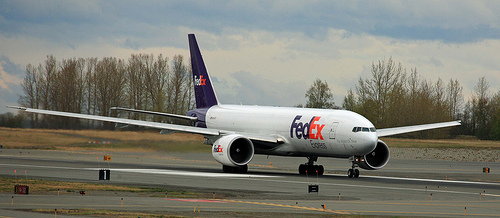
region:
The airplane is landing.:
[34, 42, 466, 189]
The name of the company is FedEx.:
[282, 114, 328, 142]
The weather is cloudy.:
[35, 6, 392, 83]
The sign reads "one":
[95, 167, 113, 184]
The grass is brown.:
[10, 130, 55, 147]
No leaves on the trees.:
[36, 60, 183, 118]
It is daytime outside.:
[38, 4, 478, 204]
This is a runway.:
[23, 135, 485, 213]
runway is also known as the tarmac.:
[76, 152, 441, 204]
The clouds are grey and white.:
[235, 15, 443, 88]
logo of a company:
[285, 111, 328, 138]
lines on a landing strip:
[221, 187, 341, 212]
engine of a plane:
[200, 127, 260, 168]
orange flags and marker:
[87, 150, 122, 185]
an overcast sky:
[270, 5, 426, 51]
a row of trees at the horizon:
[15, 35, 180, 95]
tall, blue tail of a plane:
[180, 21, 221, 106]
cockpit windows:
[346, 115, 376, 155]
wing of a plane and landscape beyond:
[391, 110, 481, 155]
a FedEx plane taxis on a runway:
[52, 5, 437, 200]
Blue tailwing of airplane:
[183, 31, 219, 104]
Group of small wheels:
[296, 163, 327, 178]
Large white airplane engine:
[206, 137, 261, 167]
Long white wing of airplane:
[10, 106, 217, 138]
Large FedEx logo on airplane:
[287, 113, 325, 139]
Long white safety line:
[398, 173, 474, 190]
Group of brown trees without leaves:
[44, 58, 84, 100]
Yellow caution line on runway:
[249, 198, 328, 210]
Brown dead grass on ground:
[6, 132, 64, 147]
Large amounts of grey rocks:
[423, 146, 480, 162]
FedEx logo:
[266, 113, 338, 149]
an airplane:
[107, 32, 418, 198]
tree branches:
[36, 61, 165, 107]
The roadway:
[351, 193, 438, 214]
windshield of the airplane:
[349, 121, 371, 134]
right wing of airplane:
[26, 112, 219, 149]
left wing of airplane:
[372, 108, 475, 136]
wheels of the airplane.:
[295, 151, 332, 173]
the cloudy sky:
[281, 12, 386, 60]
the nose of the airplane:
[351, 138, 389, 153]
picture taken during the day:
[65, 22, 463, 191]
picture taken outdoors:
[90, 24, 495, 126]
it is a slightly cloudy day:
[144, 40, 407, 86]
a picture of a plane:
[133, 59, 444, 213]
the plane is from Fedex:
[210, 91, 347, 151]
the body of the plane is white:
[128, 21, 464, 194]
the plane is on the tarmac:
[148, 61, 381, 185]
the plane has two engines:
[178, 86, 404, 210]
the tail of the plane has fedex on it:
[148, 42, 260, 144]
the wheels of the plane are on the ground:
[242, 147, 433, 204]